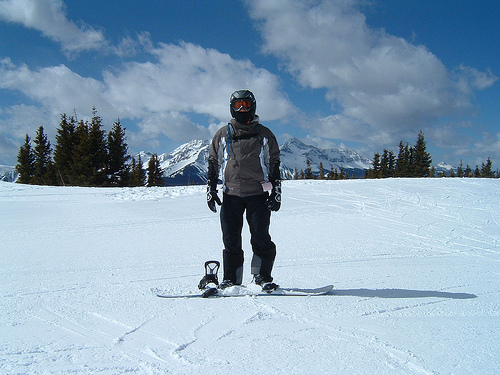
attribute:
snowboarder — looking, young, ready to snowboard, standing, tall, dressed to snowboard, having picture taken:
[203, 88, 287, 298]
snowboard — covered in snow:
[150, 282, 335, 299]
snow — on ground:
[2, 179, 499, 371]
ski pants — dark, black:
[219, 193, 274, 284]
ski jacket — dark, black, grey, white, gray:
[206, 117, 286, 195]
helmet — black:
[229, 90, 258, 124]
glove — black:
[205, 187, 221, 213]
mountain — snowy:
[122, 134, 419, 182]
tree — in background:
[16, 133, 36, 180]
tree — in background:
[32, 124, 54, 185]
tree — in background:
[54, 112, 75, 188]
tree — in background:
[75, 120, 96, 187]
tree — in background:
[105, 119, 130, 185]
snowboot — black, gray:
[219, 276, 239, 292]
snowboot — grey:
[253, 272, 276, 294]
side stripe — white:
[255, 133, 272, 188]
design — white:
[204, 186, 211, 204]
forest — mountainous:
[21, 110, 500, 181]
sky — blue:
[2, 3, 498, 166]